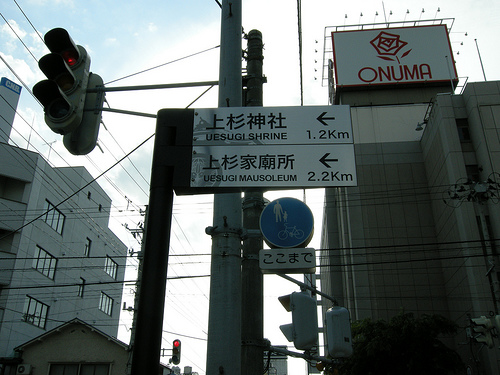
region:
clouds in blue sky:
[11, 2, 495, 122]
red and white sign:
[331, 23, 455, 93]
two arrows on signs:
[316, 111, 341, 170]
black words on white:
[203, 131, 287, 143]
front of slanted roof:
[15, 314, 130, 374]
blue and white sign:
[261, 197, 315, 248]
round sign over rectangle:
[257, 196, 317, 271]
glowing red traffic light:
[171, 338, 181, 365]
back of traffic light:
[322, 298, 353, 365]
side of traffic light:
[278, 289, 317, 344]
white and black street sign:
[191, 108, 354, 190]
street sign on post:
[191, 107, 351, 188]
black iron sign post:
[128, 108, 183, 366]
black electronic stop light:
[36, 30, 107, 156]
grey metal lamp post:
[206, 0, 241, 373]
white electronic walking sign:
[279, 293, 316, 350]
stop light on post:
[172, 339, 182, 364]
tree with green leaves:
[326, 318, 484, 373]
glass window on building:
[41, 198, 66, 234]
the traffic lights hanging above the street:
[31, 28, 220, 155]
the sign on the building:
[330, 24, 458, 84]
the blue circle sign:
[260, 197, 314, 246]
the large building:
[0, 74, 129, 356]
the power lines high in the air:
[0, 0, 496, 374]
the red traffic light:
[172, 338, 179, 348]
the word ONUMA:
[357, 62, 432, 82]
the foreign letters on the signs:
[200, 113, 312, 263]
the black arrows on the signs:
[316, 108, 338, 169]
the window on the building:
[32, 239, 58, 279]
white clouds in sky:
[0, 5, 491, 179]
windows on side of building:
[22, 197, 116, 330]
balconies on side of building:
[0, 145, 39, 289]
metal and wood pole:
[206, 2, 261, 369]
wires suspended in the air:
[0, 178, 498, 300]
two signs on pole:
[133, 103, 356, 372]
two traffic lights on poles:
[263, 280, 352, 363]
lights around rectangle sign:
[313, 8, 467, 87]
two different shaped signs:
[258, 192, 316, 272]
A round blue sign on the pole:
[257, 185, 326, 253]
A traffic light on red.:
[165, 324, 187, 367]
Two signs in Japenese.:
[186, 109, 349, 186]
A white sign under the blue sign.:
[255, 241, 335, 278]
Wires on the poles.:
[324, 187, 498, 273]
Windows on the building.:
[37, 201, 103, 298]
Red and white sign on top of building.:
[327, 17, 471, 112]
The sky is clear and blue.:
[91, 16, 207, 78]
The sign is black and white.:
[183, 106, 338, 181]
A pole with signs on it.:
[133, 96, 193, 295]